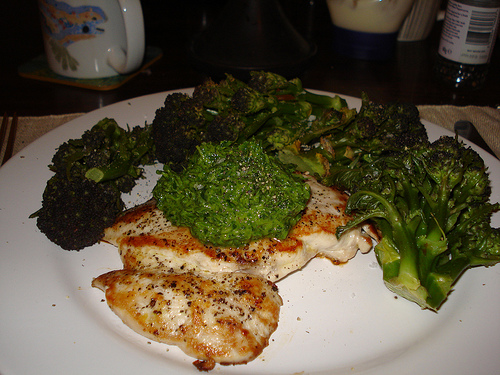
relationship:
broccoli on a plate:
[349, 136, 499, 312] [1, 87, 498, 373]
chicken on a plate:
[92, 172, 379, 371] [1, 87, 498, 373]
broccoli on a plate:
[39, 176, 124, 252] [1, 87, 498, 373]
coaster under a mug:
[17, 41, 162, 91] [39, 3, 145, 81]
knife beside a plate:
[453, 121, 497, 160] [1, 87, 498, 373]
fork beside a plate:
[0, 106, 21, 168] [1, 87, 498, 373]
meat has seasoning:
[92, 172, 379, 371] [145, 280, 254, 320]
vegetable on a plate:
[37, 66, 498, 307] [1, 87, 498, 373]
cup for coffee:
[39, 3, 145, 81] [39, 3, 145, 81]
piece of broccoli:
[149, 91, 202, 163] [147, 73, 354, 167]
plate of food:
[1, 87, 498, 373] [37, 69, 497, 368]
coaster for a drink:
[17, 41, 162, 91] [39, 3, 145, 81]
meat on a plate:
[93, 269, 284, 372] [1, 87, 498, 373]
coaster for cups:
[17, 41, 162, 91] [39, 3, 145, 81]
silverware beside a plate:
[0, 106, 21, 168] [1, 87, 498, 373]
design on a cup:
[41, 1, 106, 71] [39, 3, 145, 81]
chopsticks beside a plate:
[1, 103, 19, 169] [1, 87, 498, 373]